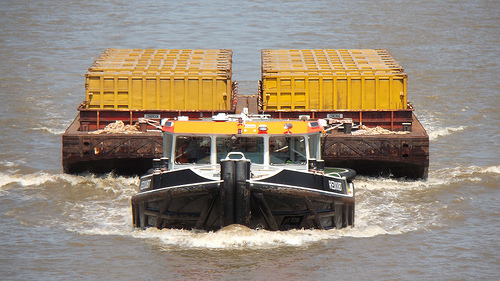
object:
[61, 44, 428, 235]
tugboat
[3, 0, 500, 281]
water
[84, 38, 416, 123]
stuff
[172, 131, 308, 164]
windows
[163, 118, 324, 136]
top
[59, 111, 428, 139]
items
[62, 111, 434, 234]
front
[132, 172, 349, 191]
writing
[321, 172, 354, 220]
side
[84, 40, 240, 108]
container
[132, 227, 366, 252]
waves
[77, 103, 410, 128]
supports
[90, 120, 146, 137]
rope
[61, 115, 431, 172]
deck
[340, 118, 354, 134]
barrel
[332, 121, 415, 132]
floor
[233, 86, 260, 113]
bridge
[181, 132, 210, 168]
person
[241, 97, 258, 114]
post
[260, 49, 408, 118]
containers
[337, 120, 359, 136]
black